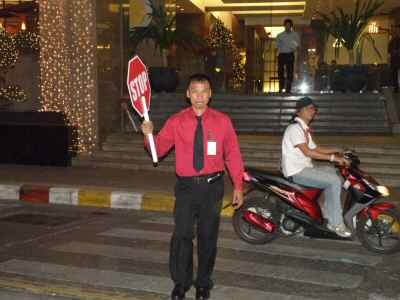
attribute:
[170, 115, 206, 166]
tie — long 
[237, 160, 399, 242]
motorcycle — the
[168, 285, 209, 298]
shoes — dark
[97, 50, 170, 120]
sign — the, stop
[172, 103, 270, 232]
shirt — red 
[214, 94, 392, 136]
building — the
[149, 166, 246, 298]
pants — long , black 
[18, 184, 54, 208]
block — red 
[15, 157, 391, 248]
sidewalk — yellow, red , white 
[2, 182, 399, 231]
curb — yellow, white , red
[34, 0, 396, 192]
building — the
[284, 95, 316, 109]
hat — a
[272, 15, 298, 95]
man — a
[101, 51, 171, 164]
sign — small 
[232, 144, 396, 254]
motorcycle — red, black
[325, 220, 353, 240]
sneakers — blue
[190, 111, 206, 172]
tie — black 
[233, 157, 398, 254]
bike — red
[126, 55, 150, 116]
stop sign — red, white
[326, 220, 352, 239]
sneaker — white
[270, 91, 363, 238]
man — the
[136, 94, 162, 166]
handle — white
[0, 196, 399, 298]
road — the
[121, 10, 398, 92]
lobby — Luxurious 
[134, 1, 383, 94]
plants — exotic 